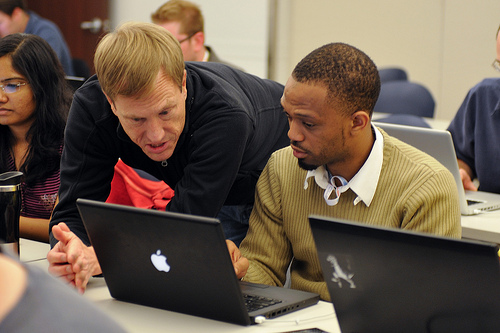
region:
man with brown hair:
[75, 18, 204, 156]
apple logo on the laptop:
[125, 238, 189, 293]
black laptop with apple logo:
[98, 212, 217, 314]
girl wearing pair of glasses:
[0, 63, 48, 118]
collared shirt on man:
[320, 129, 400, 223]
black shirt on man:
[188, 68, 276, 155]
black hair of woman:
[21, 57, 63, 124]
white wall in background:
[413, 14, 464, 54]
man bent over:
[68, 54, 265, 217]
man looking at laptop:
[267, 49, 406, 231]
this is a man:
[261, 52, 451, 212]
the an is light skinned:
[321, 123, 343, 145]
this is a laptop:
[103, 229, 245, 309]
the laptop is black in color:
[181, 270, 222, 287]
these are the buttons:
[248, 290, 260, 305]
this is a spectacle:
[4, 81, 26, 96]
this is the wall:
[385, 5, 435, 35]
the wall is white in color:
[393, 10, 441, 35]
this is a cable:
[264, 316, 314, 328]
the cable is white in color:
[272, 314, 293, 330]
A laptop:
[185, 219, 287, 294]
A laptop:
[164, 221, 204, 268]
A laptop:
[147, 193, 221, 274]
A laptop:
[151, 191, 253, 313]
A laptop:
[181, 233, 266, 331]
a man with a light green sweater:
[235, 48, 450, 292]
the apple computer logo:
[145, 247, 176, 277]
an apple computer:
[72, 192, 314, 330]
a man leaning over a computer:
[85, 23, 207, 175]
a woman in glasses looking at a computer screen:
[2, 32, 81, 162]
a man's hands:
[34, 212, 115, 287]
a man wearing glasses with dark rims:
[158, 2, 222, 61]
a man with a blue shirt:
[6, 4, 79, 81]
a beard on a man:
[291, 142, 334, 179]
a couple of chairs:
[376, 57, 436, 124]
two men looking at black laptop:
[48, 17, 405, 192]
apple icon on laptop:
[142, 237, 192, 285]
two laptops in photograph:
[4, 177, 471, 314]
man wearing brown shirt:
[280, 70, 434, 271]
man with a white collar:
[258, 134, 403, 211]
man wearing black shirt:
[48, 4, 248, 159]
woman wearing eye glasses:
[2, 54, 37, 142]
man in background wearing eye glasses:
[138, 5, 220, 67]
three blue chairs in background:
[348, 51, 469, 202]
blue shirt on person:
[411, 27, 496, 151]